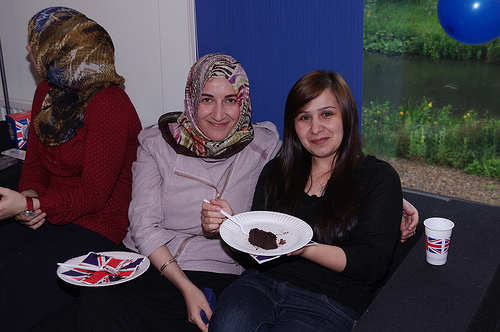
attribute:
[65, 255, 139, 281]
napkin — red, white, and blue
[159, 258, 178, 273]
band — silver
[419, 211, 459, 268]
cup — white, red, blue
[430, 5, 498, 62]
balloon — blue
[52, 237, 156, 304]
plate — paper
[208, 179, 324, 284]
plate. — white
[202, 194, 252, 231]
fork — plastic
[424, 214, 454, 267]
cup — paper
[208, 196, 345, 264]
plate — white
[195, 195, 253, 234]
fork — white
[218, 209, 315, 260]
plate — white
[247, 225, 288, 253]
food — brown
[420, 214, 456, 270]
cup — white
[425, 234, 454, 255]
design — red and blue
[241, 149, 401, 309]
shirt — black